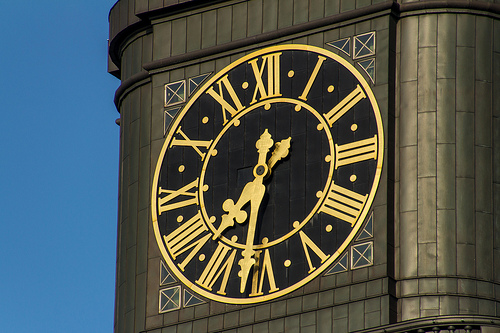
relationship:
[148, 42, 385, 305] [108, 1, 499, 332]
clock on tower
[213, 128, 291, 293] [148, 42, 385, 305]
hands on clock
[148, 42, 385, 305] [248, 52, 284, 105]
clock with roman numerals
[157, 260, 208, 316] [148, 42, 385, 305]
decorative corner by clock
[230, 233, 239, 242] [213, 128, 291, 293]
circle between clock hands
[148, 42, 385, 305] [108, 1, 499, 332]
clock on building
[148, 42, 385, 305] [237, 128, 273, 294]
clock has minute hand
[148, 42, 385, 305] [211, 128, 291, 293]
clock has hands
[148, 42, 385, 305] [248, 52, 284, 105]
clock has roman numerals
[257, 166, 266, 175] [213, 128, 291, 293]
screw holding hands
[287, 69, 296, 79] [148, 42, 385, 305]
gold dot on clock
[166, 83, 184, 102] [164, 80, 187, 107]
x in square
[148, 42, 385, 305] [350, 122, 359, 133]
clock has dot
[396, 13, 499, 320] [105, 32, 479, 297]
bricks on column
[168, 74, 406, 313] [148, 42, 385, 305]
background of clock